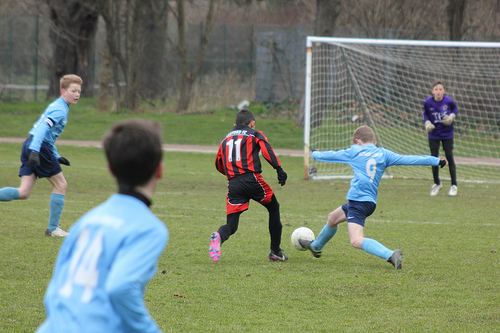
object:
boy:
[422, 80, 458, 196]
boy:
[209, 109, 288, 262]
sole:
[208, 231, 221, 262]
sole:
[386, 249, 403, 270]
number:
[226, 139, 242, 162]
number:
[366, 158, 377, 183]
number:
[57, 231, 105, 304]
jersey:
[312, 143, 441, 204]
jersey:
[215, 125, 282, 180]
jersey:
[28, 96, 70, 159]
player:
[0, 74, 83, 236]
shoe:
[449, 184, 458, 196]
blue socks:
[361, 237, 395, 260]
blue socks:
[310, 223, 338, 251]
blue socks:
[47, 192, 65, 232]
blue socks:
[0, 186, 21, 202]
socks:
[47, 193, 64, 232]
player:
[298, 125, 447, 269]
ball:
[291, 226, 315, 251]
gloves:
[276, 167, 288, 187]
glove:
[28, 151, 41, 167]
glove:
[57, 156, 70, 166]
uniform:
[215, 124, 282, 215]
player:
[210, 110, 291, 262]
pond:
[6, 78, 129, 98]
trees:
[165, 0, 298, 105]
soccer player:
[423, 80, 458, 196]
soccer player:
[32, 120, 169, 333]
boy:
[298, 125, 446, 269]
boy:
[0, 74, 83, 237]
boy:
[35, 118, 170, 333]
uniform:
[33, 186, 170, 332]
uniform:
[0, 95, 70, 236]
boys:
[0, 99, 500, 333]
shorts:
[226, 172, 274, 215]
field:
[0, 101, 497, 333]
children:
[0, 74, 460, 333]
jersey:
[422, 94, 458, 139]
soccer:
[290, 226, 315, 252]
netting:
[302, 36, 499, 186]